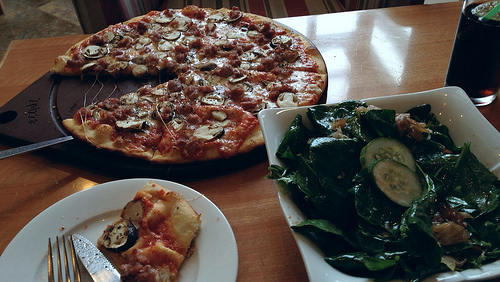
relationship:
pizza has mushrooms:
[49, 6, 329, 163] [111, 26, 282, 137]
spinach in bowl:
[317, 139, 352, 198] [417, 68, 474, 117]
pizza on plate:
[49, 6, 329, 163] [5, 173, 243, 279]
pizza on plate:
[97, 183, 199, 278] [255, 88, 498, 278]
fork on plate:
[45, 233, 85, 281] [5, 173, 243, 279]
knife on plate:
[69, 233, 124, 282] [5, 173, 243, 279]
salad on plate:
[307, 101, 494, 266] [255, 88, 498, 278]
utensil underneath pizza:
[0, 133, 72, 158] [56, 5, 361, 183]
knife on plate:
[64, 229, 114, 280] [5, 173, 243, 279]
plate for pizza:
[1, 7, 329, 177] [49, 6, 329, 163]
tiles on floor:
[1, 0, 81, 46] [1, 2, 82, 57]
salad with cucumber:
[321, 244, 405, 279] [360, 135, 422, 207]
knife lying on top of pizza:
[69, 233, 124, 282] [91, 179, 201, 280]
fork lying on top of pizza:
[46, 234, 80, 281] [91, 179, 201, 280]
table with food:
[288, 11, 410, 76] [102, 7, 404, 192]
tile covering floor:
[6, 3, 75, 31] [1, 1, 84, 65]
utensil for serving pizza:
[0, 133, 75, 158] [49, 6, 329, 163]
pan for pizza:
[30, 73, 163, 105] [119, 17, 318, 115]